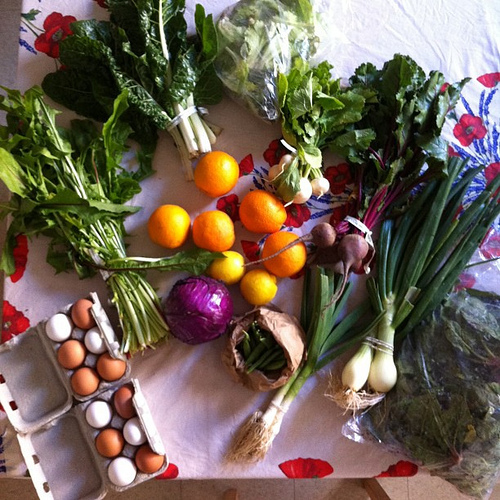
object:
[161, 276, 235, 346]
head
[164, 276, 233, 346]
cabbage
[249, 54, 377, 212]
raddishes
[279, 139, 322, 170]
bundle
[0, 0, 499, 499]
leafy greens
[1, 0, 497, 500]
vegetables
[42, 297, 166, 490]
eggs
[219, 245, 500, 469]
stalks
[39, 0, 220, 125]
leaves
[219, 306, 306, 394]
peas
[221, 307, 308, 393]
brown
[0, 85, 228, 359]
spinach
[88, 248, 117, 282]
bunch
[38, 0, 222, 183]
kale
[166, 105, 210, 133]
bunch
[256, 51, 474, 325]
beetroot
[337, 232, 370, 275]
bunch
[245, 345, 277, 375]
edamame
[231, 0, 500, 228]
light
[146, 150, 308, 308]
fruits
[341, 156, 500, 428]
green onion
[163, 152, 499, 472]
onions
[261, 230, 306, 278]
orange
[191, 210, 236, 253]
orange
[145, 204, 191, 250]
orange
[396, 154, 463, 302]
chive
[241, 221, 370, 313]
radish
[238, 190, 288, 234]
orange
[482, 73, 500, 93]
flower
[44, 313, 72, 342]
egg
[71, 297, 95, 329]
egg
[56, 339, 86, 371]
egg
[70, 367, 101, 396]
egg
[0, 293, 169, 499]
carton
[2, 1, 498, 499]
table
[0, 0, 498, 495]
table cloth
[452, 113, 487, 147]
flower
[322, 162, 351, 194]
flower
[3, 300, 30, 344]
flower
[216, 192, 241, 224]
flower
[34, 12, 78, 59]
flower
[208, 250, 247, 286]
lemon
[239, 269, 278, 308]
lemon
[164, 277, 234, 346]
onion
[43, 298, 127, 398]
half dozen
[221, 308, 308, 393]
bag